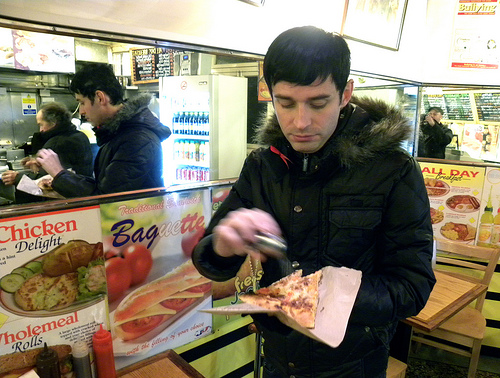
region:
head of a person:
[260, 13, 385, 152]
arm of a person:
[216, 205, 276, 275]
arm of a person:
[307, 263, 397, 336]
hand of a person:
[212, 180, 298, 264]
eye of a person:
[256, 78, 307, 120]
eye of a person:
[300, 90, 328, 109]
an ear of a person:
[335, 71, 375, 130]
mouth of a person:
[279, 126, 317, 143]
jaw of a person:
[295, 142, 324, 149]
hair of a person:
[260, 20, 336, 70]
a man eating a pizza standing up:
[198, 24, 445, 374]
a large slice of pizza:
[227, 267, 329, 342]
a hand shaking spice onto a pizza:
[212, 207, 360, 349]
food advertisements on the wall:
[1, 191, 206, 363]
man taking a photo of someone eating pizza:
[414, 99, 456, 163]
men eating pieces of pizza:
[4, 72, 184, 215]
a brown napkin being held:
[317, 271, 366, 346]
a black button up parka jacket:
[215, 152, 429, 377]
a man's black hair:
[249, 26, 351, 91]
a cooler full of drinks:
[165, 79, 217, 184]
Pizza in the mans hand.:
[230, 264, 401, 341]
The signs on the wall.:
[6, 211, 219, 356]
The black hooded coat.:
[198, 133, 441, 361]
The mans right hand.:
[217, 200, 284, 267]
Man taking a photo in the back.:
[420, 104, 447, 152]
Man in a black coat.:
[27, 101, 89, 191]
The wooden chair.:
[422, 231, 492, 369]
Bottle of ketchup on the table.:
[92, 325, 124, 376]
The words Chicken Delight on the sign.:
[0, 220, 79, 251]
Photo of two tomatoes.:
[109, 243, 154, 298]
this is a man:
[189, 22, 438, 377]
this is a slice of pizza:
[236, 265, 327, 331]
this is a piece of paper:
[198, 261, 365, 350]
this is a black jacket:
[188, 91, 438, 376]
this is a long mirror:
[0, 18, 426, 233]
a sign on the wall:
[0, 208, 110, 363]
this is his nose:
[291, 110, 312, 132]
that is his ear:
[340, 78, 357, 107]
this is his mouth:
[282, 130, 317, 143]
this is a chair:
[391, 236, 498, 376]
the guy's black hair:
[263, 29, 351, 83]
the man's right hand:
[214, 201, 287, 265]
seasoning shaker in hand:
[247, 225, 289, 257]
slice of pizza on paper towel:
[245, 273, 332, 341]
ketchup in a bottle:
[90, 324, 123, 376]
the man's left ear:
[338, 72, 359, 110]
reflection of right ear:
[93, 90, 110, 108]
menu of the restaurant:
[128, 48, 178, 82]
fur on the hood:
[246, 96, 402, 155]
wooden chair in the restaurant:
[414, 234, 497, 376]